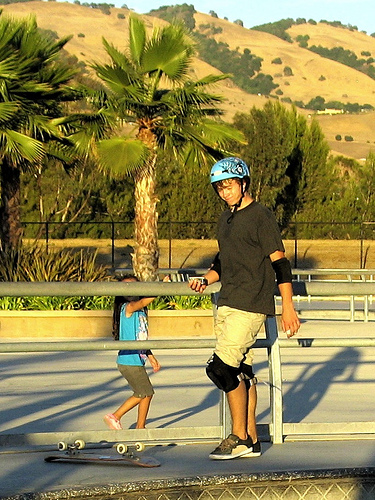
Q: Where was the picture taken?
A: At a skatepark.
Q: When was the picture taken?
A: Daytime.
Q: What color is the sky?
A: Blue.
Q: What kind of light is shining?
A: Sunlight.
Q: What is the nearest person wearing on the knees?
A: Kneepads.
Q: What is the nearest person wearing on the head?
A: A helmet.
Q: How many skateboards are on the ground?
A: One.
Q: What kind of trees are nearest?
A: Palm trees.